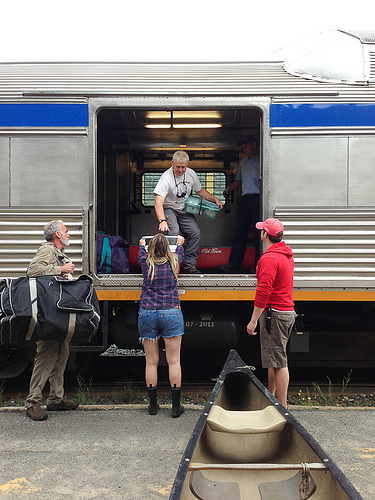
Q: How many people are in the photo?
A: Five.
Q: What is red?
A: Man's sweatshirt.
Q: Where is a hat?
A: On man's head.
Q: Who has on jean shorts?
A: Woman.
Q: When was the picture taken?
A: Daytime.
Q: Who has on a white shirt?
A: Man on train.